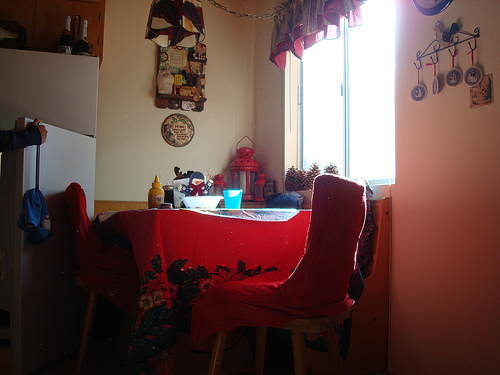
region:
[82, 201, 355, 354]
a red tablecloth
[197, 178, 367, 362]
a red slip cover on a chair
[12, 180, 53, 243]
blue towel on refrigerator door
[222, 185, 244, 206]
blue cup on table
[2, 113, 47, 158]
person opening the fridge up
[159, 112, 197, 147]
a round wall decoration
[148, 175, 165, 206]
a short round yellow squeeze bottle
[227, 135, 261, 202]
a red lantern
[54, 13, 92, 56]
champagne bottles on fridge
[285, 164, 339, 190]
four pine cones in the windowsill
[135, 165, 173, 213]
a yellow plastic bottle of mustard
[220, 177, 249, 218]
a blue plastic cup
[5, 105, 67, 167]
a person holding a refrigerator door open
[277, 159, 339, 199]
pine cones on a window sill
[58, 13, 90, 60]
two bottles of wine on to of a refrigerator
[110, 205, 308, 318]
a red table cloth with a floral print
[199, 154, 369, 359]
a wood chair with a red cover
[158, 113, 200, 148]
a round plaque hanging on the wall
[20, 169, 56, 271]
a blue towel hanging on a refrigerator door handle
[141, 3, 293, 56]
a lamp hanging from the cieling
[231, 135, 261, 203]
a red painted lantern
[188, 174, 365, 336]
a red cover on a kitchen chair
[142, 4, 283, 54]
a suspended chain running to a light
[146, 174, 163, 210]
a yellow container with a pointed top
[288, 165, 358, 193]
pine cones on the windowsill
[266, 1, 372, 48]
curtain on the window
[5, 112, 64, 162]
a hand gripping a refrigerator handle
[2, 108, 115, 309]
an open refrigerator door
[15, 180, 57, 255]
a blue towel hanging on a refrigerator handle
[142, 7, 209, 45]
stained glass lampshade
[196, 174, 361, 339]
a red slip on wooden chair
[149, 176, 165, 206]
small yellow squeeze bottle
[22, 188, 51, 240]
blue towel hanging on fridge door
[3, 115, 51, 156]
person opening refrigerator door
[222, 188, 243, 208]
a light blue cup on table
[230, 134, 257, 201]
a red lantern in corner of table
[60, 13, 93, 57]
bottles of champagne on top of fridge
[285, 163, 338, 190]
brown pine cones in windowsill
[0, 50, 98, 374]
the refrigerator next to the table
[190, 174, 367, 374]
the chair at the table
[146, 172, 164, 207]
the yellow bottle on the table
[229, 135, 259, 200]
the large lantern in the corner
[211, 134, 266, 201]
the lanterns in the corner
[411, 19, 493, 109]
the objects hanging on the wall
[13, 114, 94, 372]
the opened refrigerator door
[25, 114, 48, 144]
the hand on the refrigerator door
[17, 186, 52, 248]
the cloth hanging from the refrigerator door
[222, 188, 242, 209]
the blue cup on the table